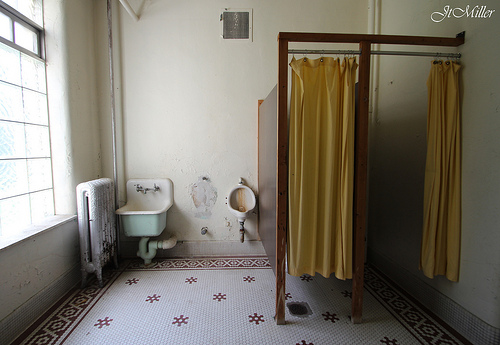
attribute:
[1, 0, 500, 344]
bathroom — old, missing a toilet, small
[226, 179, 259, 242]
urinal — rusty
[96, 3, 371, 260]
wall — white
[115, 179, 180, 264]
sink — white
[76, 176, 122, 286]
radiator — rusty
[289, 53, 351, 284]
curtain — hanging, yellow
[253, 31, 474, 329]
stall — wooden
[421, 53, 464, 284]
curtain — open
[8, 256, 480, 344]
tile — flower print, patterned, floor, design , floral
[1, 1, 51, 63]
window — light  , shining , through , small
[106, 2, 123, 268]
pole — silver, long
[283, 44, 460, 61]
rod — metal